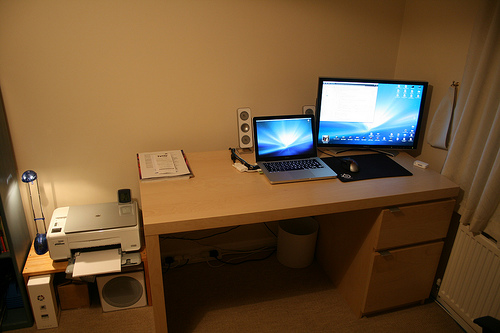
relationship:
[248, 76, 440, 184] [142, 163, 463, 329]
monitors on desk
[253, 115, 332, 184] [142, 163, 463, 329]
laptop on desk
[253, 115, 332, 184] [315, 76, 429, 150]
laptop beside monitor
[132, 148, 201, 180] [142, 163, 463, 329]
papers on desk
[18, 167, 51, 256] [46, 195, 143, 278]
lamp beside printer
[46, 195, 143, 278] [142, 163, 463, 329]
printer beside desk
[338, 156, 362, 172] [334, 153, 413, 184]
mouse on pad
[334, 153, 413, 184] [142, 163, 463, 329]
pad on desk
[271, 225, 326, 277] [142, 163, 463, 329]
basket under desk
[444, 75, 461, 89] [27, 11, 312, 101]
hook on wall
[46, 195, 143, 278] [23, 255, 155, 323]
printer on tray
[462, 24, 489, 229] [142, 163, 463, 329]
curtains beside desk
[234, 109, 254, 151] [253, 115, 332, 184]
speakers beside laptop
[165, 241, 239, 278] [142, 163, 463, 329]
powerstrip under desk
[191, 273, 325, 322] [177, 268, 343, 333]
shadow on floor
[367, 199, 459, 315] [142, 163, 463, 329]
drawers in desk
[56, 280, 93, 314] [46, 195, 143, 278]
box under printer